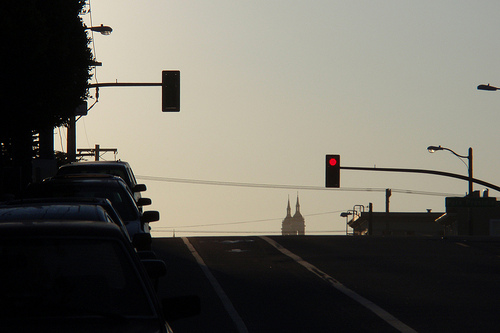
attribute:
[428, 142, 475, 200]
streetlight — Regular 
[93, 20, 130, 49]
light — regular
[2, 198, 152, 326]
car — Dark 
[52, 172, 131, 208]
car — Dark 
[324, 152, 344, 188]
street light — regular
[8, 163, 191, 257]
car — Parked 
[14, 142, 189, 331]
cars — Parked 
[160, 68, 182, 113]
street light — On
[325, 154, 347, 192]
street light — On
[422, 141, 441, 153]
street light — On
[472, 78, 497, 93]
street light — On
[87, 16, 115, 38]
street light — On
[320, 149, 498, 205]
street light — Tall